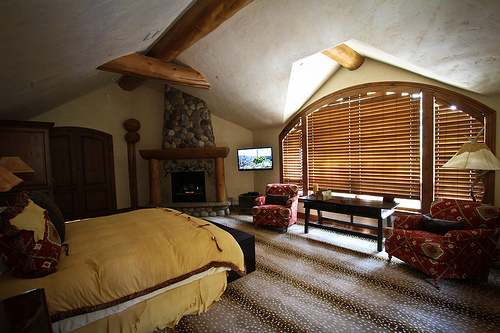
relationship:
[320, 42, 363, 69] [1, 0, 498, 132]
beam in ceiling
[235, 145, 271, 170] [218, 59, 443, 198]
tv on wall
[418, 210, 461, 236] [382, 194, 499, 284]
pillow on chair